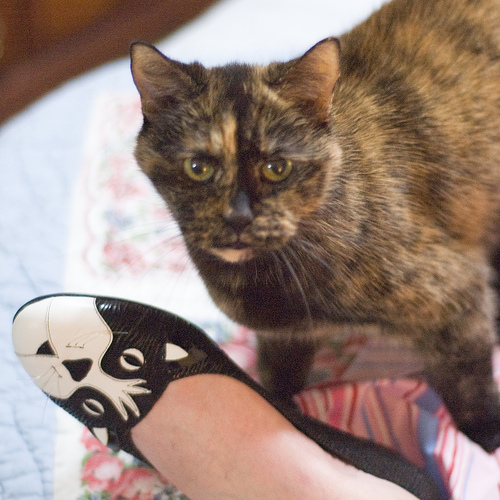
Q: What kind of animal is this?
A: Cat.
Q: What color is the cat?
A: Brown and black.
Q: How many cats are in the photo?
A: One.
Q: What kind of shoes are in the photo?
A: Flats.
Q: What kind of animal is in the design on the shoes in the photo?
A: Cat.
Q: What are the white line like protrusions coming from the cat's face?
A: Whiskers.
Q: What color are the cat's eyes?
A: Yellow and black.